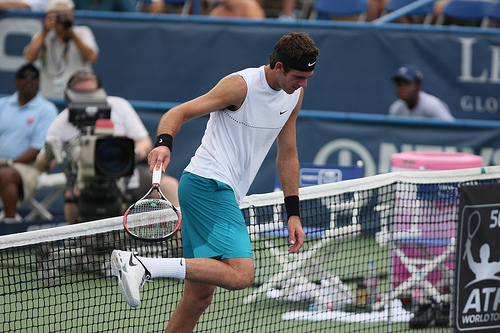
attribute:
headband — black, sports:
[272, 50, 318, 70]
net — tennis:
[20, 171, 482, 321]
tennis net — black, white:
[9, 171, 481, 325]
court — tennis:
[25, 125, 472, 317]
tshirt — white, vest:
[180, 67, 307, 200]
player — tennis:
[101, 30, 325, 328]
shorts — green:
[178, 168, 258, 261]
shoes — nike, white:
[108, 247, 150, 313]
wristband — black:
[281, 191, 303, 217]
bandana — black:
[271, 45, 318, 73]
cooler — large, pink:
[394, 140, 479, 303]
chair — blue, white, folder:
[240, 158, 363, 309]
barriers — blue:
[1, 6, 481, 235]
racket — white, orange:
[119, 158, 183, 242]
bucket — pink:
[386, 146, 482, 320]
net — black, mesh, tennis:
[3, 162, 499, 329]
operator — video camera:
[38, 60, 152, 271]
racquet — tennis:
[116, 169, 193, 248]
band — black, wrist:
[277, 192, 302, 224]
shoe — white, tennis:
[108, 244, 151, 314]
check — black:
[121, 249, 142, 269]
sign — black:
[449, 172, 499, 332]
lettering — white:
[464, 205, 498, 325]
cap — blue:
[390, 58, 429, 86]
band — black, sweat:
[267, 41, 328, 73]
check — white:
[302, 59, 316, 69]